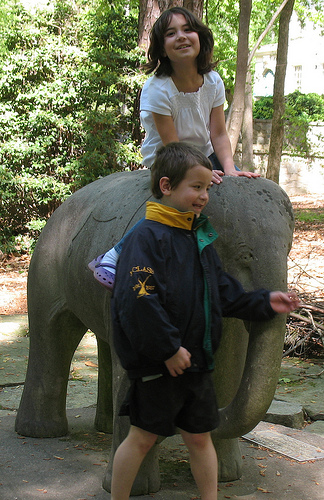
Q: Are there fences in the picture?
A: No, there are no fences.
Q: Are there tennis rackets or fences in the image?
A: No, there are no fences or tennis rackets.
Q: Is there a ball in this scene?
A: No, there are no balls.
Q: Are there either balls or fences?
A: No, there are no balls or fences.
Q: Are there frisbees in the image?
A: No, there are no frisbees.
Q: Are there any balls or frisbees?
A: No, there are no frisbees or balls.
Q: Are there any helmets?
A: No, there are no helmets.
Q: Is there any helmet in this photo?
A: No, there are no helmets.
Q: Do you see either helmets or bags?
A: No, there are no helmets or bags.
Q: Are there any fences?
A: No, there are no fences.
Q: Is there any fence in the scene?
A: No, there are no fences.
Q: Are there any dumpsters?
A: No, there are no dumpsters.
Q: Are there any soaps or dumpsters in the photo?
A: No, there are no dumpsters or soaps.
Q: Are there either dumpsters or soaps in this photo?
A: No, there are no dumpsters or soaps.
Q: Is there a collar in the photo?
A: Yes, there is a collar.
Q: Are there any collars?
A: Yes, there is a collar.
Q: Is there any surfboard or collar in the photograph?
A: Yes, there is a collar.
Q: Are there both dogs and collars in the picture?
A: No, there is a collar but no dogs.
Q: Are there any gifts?
A: No, there are no gifts.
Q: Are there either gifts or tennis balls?
A: No, there are no gifts or tennis balls.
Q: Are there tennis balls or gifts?
A: No, there are no gifts or tennis balls.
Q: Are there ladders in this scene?
A: No, there are no ladders.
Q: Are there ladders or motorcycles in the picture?
A: No, there are no ladders or motorcycles.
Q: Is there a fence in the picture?
A: No, there are no fences.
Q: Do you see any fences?
A: No, there are no fences.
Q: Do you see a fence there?
A: No, there are no fences.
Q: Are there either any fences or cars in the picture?
A: No, there are no fences or cars.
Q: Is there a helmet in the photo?
A: No, there are no helmets.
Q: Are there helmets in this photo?
A: No, there are no helmets.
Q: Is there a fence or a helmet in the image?
A: No, there are no helmets or fences.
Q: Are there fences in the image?
A: No, there are no fences.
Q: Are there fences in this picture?
A: No, there are no fences.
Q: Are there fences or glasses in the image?
A: No, there are no fences or glasses.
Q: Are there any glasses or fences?
A: No, there are no fences or glasses.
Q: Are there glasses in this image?
A: No, there are no glasses.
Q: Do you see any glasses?
A: No, there are no glasses.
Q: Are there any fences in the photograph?
A: No, there are no fences.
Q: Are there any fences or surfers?
A: No, there are no fences or surfers.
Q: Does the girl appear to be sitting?
A: Yes, the girl is sitting.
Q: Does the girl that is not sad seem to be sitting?
A: Yes, the girl is sitting.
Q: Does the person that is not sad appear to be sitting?
A: Yes, the girl is sitting.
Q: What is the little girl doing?
A: The girl is sitting.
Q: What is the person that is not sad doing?
A: The girl is sitting.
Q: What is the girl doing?
A: The girl is sitting.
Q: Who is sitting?
A: The girl is sitting.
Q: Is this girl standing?
A: No, the girl is sitting.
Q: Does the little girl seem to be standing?
A: No, the girl is sitting.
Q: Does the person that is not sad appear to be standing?
A: No, the girl is sitting.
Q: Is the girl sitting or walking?
A: The girl is sitting.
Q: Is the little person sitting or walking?
A: The girl is sitting.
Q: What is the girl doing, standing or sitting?
A: The girl is sitting.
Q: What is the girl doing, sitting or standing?
A: The girl is sitting.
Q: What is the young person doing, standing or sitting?
A: The girl is sitting.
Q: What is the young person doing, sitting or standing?
A: The girl is sitting.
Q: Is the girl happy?
A: Yes, the girl is happy.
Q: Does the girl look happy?
A: Yes, the girl is happy.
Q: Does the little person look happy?
A: Yes, the girl is happy.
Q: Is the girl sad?
A: No, the girl is happy.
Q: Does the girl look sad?
A: No, the girl is happy.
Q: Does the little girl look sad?
A: No, the girl is happy.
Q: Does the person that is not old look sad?
A: No, the girl is happy.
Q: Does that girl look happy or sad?
A: The girl is happy.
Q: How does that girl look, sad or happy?
A: The girl is happy.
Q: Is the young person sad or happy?
A: The girl is happy.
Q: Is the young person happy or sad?
A: The girl is happy.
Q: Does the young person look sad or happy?
A: The girl is happy.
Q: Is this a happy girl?
A: Yes, this is a happy girl.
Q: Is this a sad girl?
A: No, this is a happy girl.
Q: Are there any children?
A: Yes, there is a child.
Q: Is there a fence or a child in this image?
A: Yes, there is a child.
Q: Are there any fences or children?
A: Yes, there is a child.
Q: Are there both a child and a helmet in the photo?
A: No, there is a child but no helmets.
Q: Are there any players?
A: No, there are no players.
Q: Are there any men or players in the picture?
A: No, there are no players or men.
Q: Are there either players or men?
A: No, there are no players or men.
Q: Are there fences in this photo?
A: No, there are no fences.